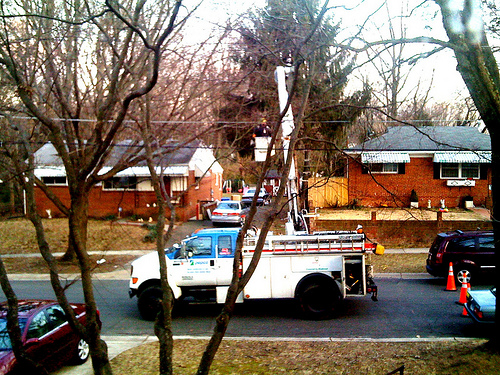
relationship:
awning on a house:
[360, 150, 410, 164] [350, 152, 441, 206]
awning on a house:
[433, 149, 491, 165] [350, 152, 441, 206]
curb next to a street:
[150, 324, 497, 372] [7, 276, 497, 338]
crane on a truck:
[265, 59, 342, 241] [120, 219, 402, 323]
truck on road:
[128, 227, 384, 318] [0, 275, 498, 340]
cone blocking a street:
[440, 259, 459, 293] [358, 254, 476, 343]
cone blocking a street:
[453, 272, 473, 302] [358, 254, 476, 343]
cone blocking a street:
[460, 295, 484, 320] [358, 254, 476, 343]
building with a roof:
[335, 125, 496, 212] [346, 124, 489, 154]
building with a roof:
[335, 125, 496, 212] [342, 120, 492, 156]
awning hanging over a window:
[429, 149, 484, 168] [106, 173, 145, 188]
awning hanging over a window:
[360, 146, 414, 162] [106, 173, 145, 188]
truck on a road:
[128, 227, 384, 318] [0, 258, 498, 340]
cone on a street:
[444, 261, 459, 292] [0, 274, 499, 344]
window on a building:
[431, 155, 481, 182] [331, 128, 494, 226]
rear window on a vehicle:
[217, 200, 239, 211] [210, 199, 245, 224]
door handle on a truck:
[208, 260, 214, 270] [126, 226, 384, 322]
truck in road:
[128, 227, 384, 318] [19, 262, 499, 362]